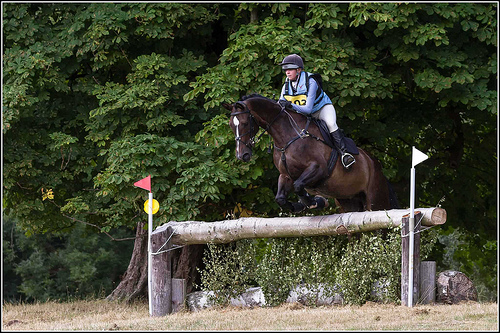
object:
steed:
[227, 93, 407, 223]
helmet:
[274, 51, 303, 68]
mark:
[232, 115, 241, 134]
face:
[217, 97, 257, 166]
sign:
[141, 199, 159, 214]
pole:
[146, 193, 154, 319]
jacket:
[289, 80, 339, 116]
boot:
[318, 120, 354, 166]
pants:
[311, 103, 348, 152]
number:
[291, 98, 307, 107]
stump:
[146, 224, 172, 313]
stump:
[167, 243, 205, 312]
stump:
[420, 257, 439, 303]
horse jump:
[112, 203, 472, 313]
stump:
[139, 207, 453, 250]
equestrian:
[256, 49, 356, 143]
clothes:
[278, 79, 341, 122]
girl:
[276, 53, 337, 124]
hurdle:
[183, 179, 351, 269]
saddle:
[313, 113, 360, 155]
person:
[276, 52, 355, 168]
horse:
[225, 91, 390, 220]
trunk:
[157, 203, 447, 244]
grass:
[4, 298, 499, 331]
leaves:
[154, 65, 159, 70]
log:
[154, 202, 448, 252]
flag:
[130, 168, 152, 193]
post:
[405, 162, 417, 307]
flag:
[407, 145, 433, 172]